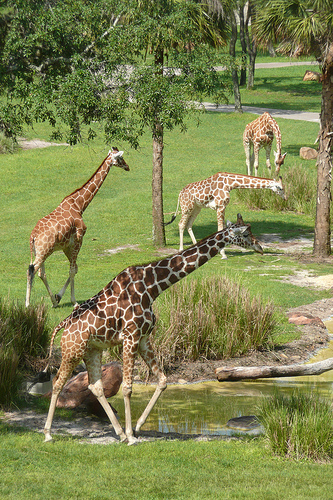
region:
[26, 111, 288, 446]
Four endangered Rothschild's giraffe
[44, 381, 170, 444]
Rothchild's giraffe are white to the knee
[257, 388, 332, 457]
tall green grass area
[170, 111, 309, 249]
giraffe bend over to drink water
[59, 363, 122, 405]
large boulder by water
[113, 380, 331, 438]
shallow sun dappled water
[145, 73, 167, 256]
trunk of a younger tree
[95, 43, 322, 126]
a grey pathway through the grounds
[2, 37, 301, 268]
a manicured green lawn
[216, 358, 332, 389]
a log lays along the water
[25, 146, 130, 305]
A very tall girafe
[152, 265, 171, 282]
A spot on a girafe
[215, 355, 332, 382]
A long log going across the water.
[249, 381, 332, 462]
A tuft of tall grass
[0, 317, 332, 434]
Green water in pond.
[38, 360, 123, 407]
A large red rock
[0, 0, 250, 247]
A tree in the middle of the grass.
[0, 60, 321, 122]
A concrete walk way.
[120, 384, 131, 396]
Knee of a giraffe.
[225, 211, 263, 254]
Head of a giraffe.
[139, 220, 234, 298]
giraffe's neck is long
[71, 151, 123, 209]
giraffe's neck is long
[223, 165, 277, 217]
giraffe's neck is long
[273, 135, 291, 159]
giraffe's neck is long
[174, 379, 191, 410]
the water is murky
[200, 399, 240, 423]
the water is murky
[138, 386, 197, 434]
the water is murky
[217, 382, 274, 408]
the water is murky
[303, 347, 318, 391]
the water is murky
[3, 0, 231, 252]
tall leafy-green tree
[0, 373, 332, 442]
creek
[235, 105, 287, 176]
giraffe with its head bent down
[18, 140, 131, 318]
giraffe walking through grass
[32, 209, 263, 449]
giraffe walking next to creek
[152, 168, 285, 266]
giraffe with its head straight out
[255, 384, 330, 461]
patch of plants in grass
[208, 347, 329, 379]
fallen log next to creek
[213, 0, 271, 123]
group of three trees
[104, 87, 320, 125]
paved walkway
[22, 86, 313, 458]
Giraffe area zoo compound.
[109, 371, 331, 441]
Murky stagnant water pool.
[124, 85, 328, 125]
Park dirt pedestrian walkway.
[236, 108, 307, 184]
Giraffe foraging food background.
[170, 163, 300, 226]
Giraffe searching area food.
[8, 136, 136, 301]
Giraffe heading towards other.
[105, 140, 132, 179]
Head horns well defined.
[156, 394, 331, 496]
Tall grass, weeds border pond.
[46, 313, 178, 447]
Knobby knees bend walking.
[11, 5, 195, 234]
Green tree leaves giraffe food.